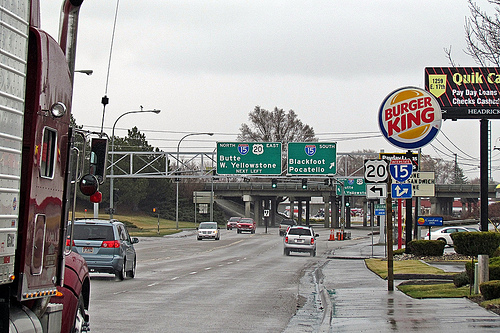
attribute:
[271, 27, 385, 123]
sky — grey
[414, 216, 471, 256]
car — white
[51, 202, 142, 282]
van — blue, mini, driving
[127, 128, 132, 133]
leaf — green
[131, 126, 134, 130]
leaf — green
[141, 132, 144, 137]
leaf — green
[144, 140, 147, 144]
leaf — green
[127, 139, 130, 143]
leaf — green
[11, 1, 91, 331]
trailer — red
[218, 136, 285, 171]
poster — GREEN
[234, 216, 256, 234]
car — red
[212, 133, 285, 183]
sign — green